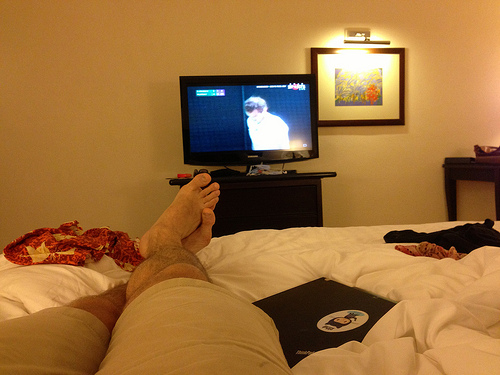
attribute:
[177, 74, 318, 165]
television — flat screen, black, on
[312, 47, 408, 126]
painting — lit, small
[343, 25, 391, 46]
light — on, bright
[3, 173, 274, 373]
legs — hairy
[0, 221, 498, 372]
blanket — white, wrinkled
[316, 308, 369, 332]
sticker — circular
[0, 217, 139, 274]
clothing — white, red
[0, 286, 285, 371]
shorts — beige, brown, seamed, tan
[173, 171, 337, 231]
stand — black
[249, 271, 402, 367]
laptop — black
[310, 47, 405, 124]
painting frame — brown, wood